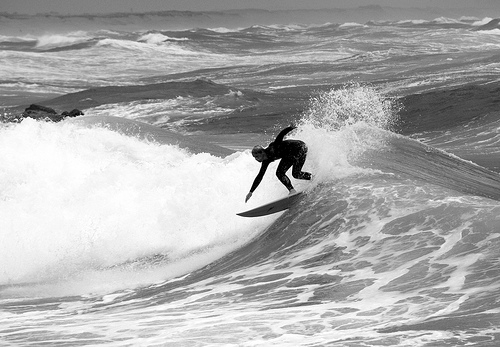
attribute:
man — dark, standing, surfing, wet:
[245, 121, 322, 204]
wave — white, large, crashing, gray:
[1, 114, 499, 307]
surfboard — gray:
[236, 188, 307, 218]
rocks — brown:
[3, 104, 84, 123]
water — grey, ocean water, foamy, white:
[1, 0, 499, 346]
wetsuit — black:
[247, 126, 313, 191]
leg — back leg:
[292, 151, 314, 180]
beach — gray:
[0, 19, 500, 36]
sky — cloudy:
[0, 0, 500, 13]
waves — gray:
[0, 14, 499, 42]